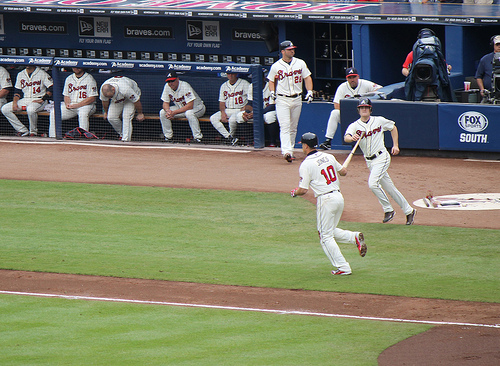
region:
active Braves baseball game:
[0, 0, 490, 363]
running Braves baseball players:
[285, 93, 420, 281]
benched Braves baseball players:
[2, 53, 268, 143]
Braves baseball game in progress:
[0, 5, 490, 281]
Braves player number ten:
[280, 130, 367, 281]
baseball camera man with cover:
[398, 25, 454, 105]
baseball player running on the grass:
[10, 130, 421, 308]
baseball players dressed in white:
[285, 95, 420, 280]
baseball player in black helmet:
[286, 125, 374, 280]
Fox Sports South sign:
[450, 109, 495, 154]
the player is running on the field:
[287, 131, 369, 276]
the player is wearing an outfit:
[302, 150, 358, 270]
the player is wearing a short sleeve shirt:
[299, 153, 340, 195]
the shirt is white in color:
[297, 150, 342, 198]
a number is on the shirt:
[320, 165, 336, 181]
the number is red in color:
[321, 162, 336, 183]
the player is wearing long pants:
[312, 188, 357, 269]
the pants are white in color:
[312, 186, 360, 269]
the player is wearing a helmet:
[297, 130, 317, 145]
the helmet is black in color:
[301, 130, 317, 146]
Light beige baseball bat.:
[340, 132, 364, 171]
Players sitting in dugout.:
[0, 58, 272, 142]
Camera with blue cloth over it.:
[400, 38, 447, 100]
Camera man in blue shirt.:
[477, 30, 499, 107]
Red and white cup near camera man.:
[463, 78, 470, 93]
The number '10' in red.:
[320, 160, 337, 187]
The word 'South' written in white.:
[453, 133, 488, 145]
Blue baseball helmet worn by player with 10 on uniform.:
[296, 128, 321, 146]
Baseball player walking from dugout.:
[265, 35, 312, 160]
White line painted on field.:
[1, 283, 498, 335]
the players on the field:
[262, 88, 418, 280]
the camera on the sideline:
[400, 33, 452, 98]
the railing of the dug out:
[1, 51, 263, 151]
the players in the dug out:
[2, 65, 274, 137]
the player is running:
[291, 126, 369, 278]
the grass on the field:
[4, 293, 434, 365]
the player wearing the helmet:
[288, 133, 320, 143]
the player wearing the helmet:
[351, 95, 374, 109]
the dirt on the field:
[3, 140, 333, 187]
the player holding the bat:
[322, 90, 429, 218]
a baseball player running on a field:
[344, 96, 415, 224]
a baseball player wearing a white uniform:
[293, 131, 367, 276]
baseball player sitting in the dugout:
[2, 65, 276, 145]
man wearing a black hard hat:
[301, 130, 320, 149]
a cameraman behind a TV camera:
[401, 27, 450, 102]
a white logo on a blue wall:
[457, 110, 489, 132]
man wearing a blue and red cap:
[164, 70, 176, 83]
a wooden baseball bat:
[341, 132, 364, 171]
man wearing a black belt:
[365, 150, 384, 160]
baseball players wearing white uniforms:
[4, 2, 416, 275]